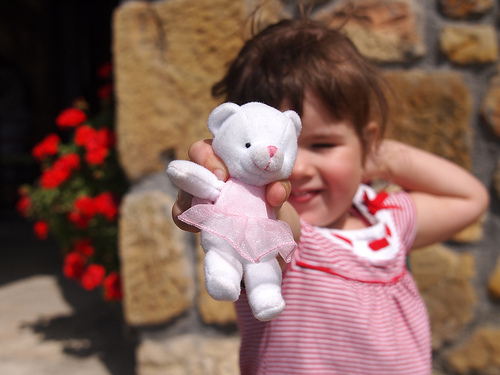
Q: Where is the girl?
A: In front of the wall.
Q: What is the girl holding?
A: A teddy bear.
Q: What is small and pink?
A: A bear.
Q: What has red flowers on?
A: The plant.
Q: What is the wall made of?
A: Rock.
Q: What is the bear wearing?
A: A pink tutu.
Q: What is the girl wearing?
A: Red and white striped shirt.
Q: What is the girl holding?
A: A bear.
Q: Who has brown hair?
A: The girl.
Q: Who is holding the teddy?
A: A girl.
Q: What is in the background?
A: Red flowers.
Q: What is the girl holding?
A: A bear.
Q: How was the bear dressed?
A: In a tutu.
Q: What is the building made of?
A: Stone.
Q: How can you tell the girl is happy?
A: She is smiling.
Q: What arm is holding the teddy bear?
A: Right.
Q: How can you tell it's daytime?
A: The sun is out.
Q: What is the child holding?
A: A teddy bear.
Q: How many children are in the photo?
A: One.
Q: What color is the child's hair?
A: Brown.